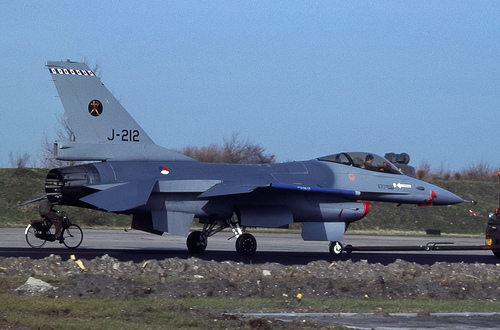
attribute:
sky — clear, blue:
[9, 12, 496, 141]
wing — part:
[212, 170, 340, 208]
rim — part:
[243, 234, 256, 250]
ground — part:
[236, 262, 260, 274]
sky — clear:
[1, 0, 499, 178]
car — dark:
[481, 201, 498, 263]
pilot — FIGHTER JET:
[349, 149, 388, 179]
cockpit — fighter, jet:
[317, 143, 414, 177]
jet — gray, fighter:
[20, 61, 481, 276]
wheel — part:
[233, 234, 257, 256]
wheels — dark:
[177, 209, 262, 264]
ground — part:
[97, 265, 213, 325]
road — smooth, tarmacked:
[0, 227, 492, 257]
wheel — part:
[328, 242, 343, 258]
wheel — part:
[186, 230, 208, 255]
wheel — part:
[61, 225, 85, 248]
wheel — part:
[23, 220, 50, 248]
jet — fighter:
[21, 51, 471, 248]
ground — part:
[280, 297, 439, 327]